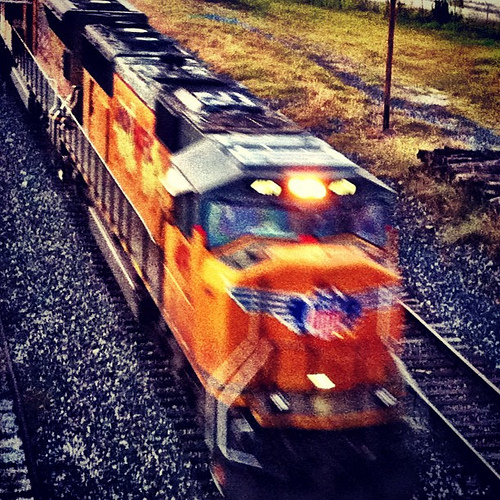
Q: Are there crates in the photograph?
A: No, there are no crates.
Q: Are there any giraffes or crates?
A: No, there are no crates or giraffes.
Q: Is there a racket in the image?
A: No, there are no rackets.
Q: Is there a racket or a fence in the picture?
A: No, there are no rackets or fences.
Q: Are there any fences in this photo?
A: No, there are no fences.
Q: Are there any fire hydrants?
A: No, there are no fire hydrants.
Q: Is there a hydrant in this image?
A: No, there are no fire hydrants.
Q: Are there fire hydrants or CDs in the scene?
A: No, there are no fire hydrants or cds.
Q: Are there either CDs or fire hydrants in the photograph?
A: No, there are no fire hydrants or cds.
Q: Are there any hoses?
A: No, there are no hoses.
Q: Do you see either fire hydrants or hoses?
A: No, there are no hoses or fire hydrants.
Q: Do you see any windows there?
A: Yes, there is a window.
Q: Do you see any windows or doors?
A: Yes, there is a window.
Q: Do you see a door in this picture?
A: No, there are no doors.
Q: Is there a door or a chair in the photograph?
A: No, there are no doors or chairs.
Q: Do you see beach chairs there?
A: No, there are no beach chairs.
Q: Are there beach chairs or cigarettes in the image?
A: No, there are no beach chairs or cigarettes.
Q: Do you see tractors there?
A: No, there are no tractors.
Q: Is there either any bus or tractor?
A: No, there are no tractors or buses.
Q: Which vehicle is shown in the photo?
A: The vehicle is a car.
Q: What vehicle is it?
A: The vehicle is a car.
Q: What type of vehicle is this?
A: That is a car.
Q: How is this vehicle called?
A: That is a car.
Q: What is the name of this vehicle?
A: That is a car.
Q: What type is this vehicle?
A: That is a car.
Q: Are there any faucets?
A: No, there are no faucets.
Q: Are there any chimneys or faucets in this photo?
A: No, there are no faucets or chimneys.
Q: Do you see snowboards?
A: No, there are no snowboards.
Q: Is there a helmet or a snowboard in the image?
A: No, there are no snowboards or helmets.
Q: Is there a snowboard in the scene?
A: No, there are no snowboards.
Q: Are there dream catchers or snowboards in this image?
A: No, there are no snowboards or dream catchers.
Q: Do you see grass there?
A: Yes, there is grass.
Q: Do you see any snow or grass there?
A: Yes, there is grass.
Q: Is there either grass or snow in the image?
A: Yes, there is grass.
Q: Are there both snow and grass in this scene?
A: No, there is grass but no snow.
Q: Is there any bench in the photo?
A: No, there are no benches.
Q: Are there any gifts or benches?
A: No, there are no benches or gifts.